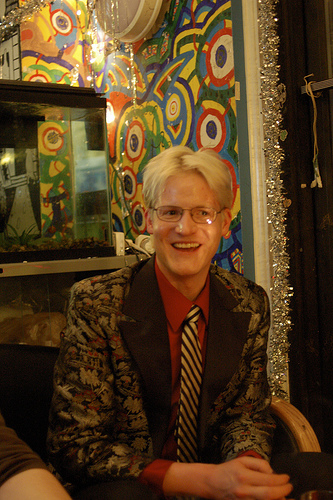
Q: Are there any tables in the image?
A: Yes, there is a table.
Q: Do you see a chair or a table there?
A: Yes, there is a table.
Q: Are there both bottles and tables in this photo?
A: No, there is a table but no bottles.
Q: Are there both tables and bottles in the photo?
A: No, there is a table but no bottles.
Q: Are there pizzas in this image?
A: No, there are no pizzas.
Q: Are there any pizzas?
A: No, there are no pizzas.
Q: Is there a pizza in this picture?
A: No, there are no pizzas.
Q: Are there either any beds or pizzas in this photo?
A: No, there are no pizzas or beds.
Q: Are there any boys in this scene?
A: No, there are no boys.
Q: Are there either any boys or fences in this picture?
A: No, there are no boys or fences.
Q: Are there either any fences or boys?
A: No, there are no boys or fences.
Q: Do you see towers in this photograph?
A: No, there are no towers.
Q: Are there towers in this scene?
A: No, there are no towers.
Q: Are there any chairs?
A: Yes, there is a chair.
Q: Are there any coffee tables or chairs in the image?
A: Yes, there is a chair.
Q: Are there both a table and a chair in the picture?
A: Yes, there are both a chair and a table.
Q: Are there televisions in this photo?
A: No, there are no televisions.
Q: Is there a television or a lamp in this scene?
A: No, there are no televisions or lamps.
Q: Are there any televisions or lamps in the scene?
A: No, there are no televisions or lamps.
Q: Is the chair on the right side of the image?
A: Yes, the chair is on the right of the image.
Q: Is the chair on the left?
A: No, the chair is on the right of the image.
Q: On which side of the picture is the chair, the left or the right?
A: The chair is on the right of the image.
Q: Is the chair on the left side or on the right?
A: The chair is on the right of the image.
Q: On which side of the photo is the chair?
A: The chair is on the right of the image.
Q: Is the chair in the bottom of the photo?
A: Yes, the chair is in the bottom of the image.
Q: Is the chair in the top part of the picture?
A: No, the chair is in the bottom of the image.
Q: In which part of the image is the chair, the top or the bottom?
A: The chair is in the bottom of the image.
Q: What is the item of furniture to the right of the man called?
A: The piece of furniture is a chair.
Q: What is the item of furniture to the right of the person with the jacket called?
A: The piece of furniture is a chair.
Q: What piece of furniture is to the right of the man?
A: The piece of furniture is a chair.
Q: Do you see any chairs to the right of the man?
A: Yes, there is a chair to the right of the man.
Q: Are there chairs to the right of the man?
A: Yes, there is a chair to the right of the man.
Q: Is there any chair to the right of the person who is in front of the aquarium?
A: Yes, there is a chair to the right of the man.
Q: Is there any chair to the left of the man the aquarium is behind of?
A: No, the chair is to the right of the man.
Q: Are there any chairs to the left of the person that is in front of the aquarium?
A: No, the chair is to the right of the man.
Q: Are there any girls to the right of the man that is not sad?
A: No, there is a chair to the right of the man.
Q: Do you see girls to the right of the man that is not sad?
A: No, there is a chair to the right of the man.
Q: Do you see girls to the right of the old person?
A: No, there is a chair to the right of the man.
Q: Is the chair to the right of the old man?
A: Yes, the chair is to the right of the man.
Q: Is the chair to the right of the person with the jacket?
A: Yes, the chair is to the right of the man.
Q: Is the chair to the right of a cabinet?
A: No, the chair is to the right of the man.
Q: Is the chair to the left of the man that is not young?
A: No, the chair is to the right of the man.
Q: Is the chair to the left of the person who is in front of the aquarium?
A: No, the chair is to the right of the man.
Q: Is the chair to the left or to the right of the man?
A: The chair is to the right of the man.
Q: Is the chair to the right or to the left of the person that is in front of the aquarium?
A: The chair is to the right of the man.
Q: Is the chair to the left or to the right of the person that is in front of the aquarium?
A: The chair is to the right of the man.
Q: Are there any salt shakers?
A: No, there are no salt shakers.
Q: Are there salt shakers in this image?
A: No, there are no salt shakers.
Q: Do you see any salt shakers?
A: No, there are no salt shakers.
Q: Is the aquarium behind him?
A: Yes, the aquarium is behind a man.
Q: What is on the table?
A: The aquarium is on the table.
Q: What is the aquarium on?
A: The aquarium is on the table.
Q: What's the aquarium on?
A: The aquarium is on the table.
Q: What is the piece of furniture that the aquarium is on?
A: The piece of furniture is a table.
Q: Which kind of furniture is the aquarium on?
A: The aquarium is on the table.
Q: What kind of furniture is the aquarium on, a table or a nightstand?
A: The aquarium is on a table.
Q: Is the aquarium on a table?
A: Yes, the aquarium is on a table.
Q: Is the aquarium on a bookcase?
A: No, the aquarium is on a table.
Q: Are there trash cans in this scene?
A: No, there are no trash cans.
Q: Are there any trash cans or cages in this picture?
A: No, there are no trash cans or cages.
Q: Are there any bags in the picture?
A: No, there are no bags.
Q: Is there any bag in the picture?
A: No, there are no bags.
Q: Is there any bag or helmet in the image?
A: No, there are no bags or helmets.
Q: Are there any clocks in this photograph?
A: Yes, there is a clock.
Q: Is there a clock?
A: Yes, there is a clock.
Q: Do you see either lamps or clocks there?
A: Yes, there is a clock.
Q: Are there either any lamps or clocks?
A: Yes, there is a clock.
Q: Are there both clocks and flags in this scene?
A: No, there is a clock but no flags.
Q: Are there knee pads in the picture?
A: No, there are no knee pads.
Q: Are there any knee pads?
A: No, there are no knee pads.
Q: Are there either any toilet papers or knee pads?
A: No, there are no knee pads or toilet papers.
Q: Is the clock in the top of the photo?
A: Yes, the clock is in the top of the image.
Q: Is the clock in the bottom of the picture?
A: No, the clock is in the top of the image.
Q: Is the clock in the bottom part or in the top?
A: The clock is in the top of the image.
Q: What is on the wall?
A: The clock is on the wall.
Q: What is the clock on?
A: The clock is on the wall.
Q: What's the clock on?
A: The clock is on the wall.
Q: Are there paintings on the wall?
A: No, there is a clock on the wall.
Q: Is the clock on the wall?
A: Yes, the clock is on the wall.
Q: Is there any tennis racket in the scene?
A: No, there are no rackets.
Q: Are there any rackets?
A: No, there are no rackets.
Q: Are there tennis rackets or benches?
A: No, there are no tennis rackets or benches.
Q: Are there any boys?
A: No, there are no boys.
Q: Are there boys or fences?
A: No, there are no boys or fences.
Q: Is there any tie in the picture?
A: Yes, there is a tie.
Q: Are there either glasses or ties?
A: Yes, there is a tie.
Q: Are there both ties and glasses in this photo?
A: Yes, there are both a tie and glasses.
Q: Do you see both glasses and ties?
A: Yes, there are both a tie and glasses.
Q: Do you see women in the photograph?
A: No, there are no women.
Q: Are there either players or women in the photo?
A: No, there are no women or players.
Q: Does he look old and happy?
A: Yes, the man is old and happy.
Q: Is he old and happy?
A: Yes, the man is old and happy.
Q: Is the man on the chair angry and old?
A: No, the man is old but happy.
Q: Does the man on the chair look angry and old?
A: No, the man is old but happy.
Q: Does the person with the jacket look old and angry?
A: No, the man is old but happy.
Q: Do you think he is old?
A: Yes, the man is old.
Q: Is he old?
A: Yes, the man is old.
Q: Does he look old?
A: Yes, the man is old.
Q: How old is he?
A: The man is old.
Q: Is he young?
A: No, the man is old.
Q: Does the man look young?
A: No, the man is old.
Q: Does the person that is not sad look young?
A: No, the man is old.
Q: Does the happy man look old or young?
A: The man is old.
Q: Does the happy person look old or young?
A: The man is old.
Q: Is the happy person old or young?
A: The man is old.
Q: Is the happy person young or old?
A: The man is old.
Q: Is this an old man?
A: Yes, this is an old man.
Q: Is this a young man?
A: No, this is an old man.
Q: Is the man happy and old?
A: Yes, the man is happy and old.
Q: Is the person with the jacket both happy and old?
A: Yes, the man is happy and old.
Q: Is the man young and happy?
A: No, the man is happy but old.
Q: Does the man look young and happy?
A: No, the man is happy but old.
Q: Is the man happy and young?
A: No, the man is happy but old.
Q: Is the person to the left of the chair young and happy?
A: No, the man is happy but old.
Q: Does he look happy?
A: Yes, the man is happy.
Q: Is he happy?
A: Yes, the man is happy.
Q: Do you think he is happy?
A: Yes, the man is happy.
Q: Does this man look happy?
A: Yes, the man is happy.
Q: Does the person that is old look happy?
A: Yes, the man is happy.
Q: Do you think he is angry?
A: No, the man is happy.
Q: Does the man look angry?
A: No, the man is happy.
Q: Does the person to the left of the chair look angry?
A: No, the man is happy.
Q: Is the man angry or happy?
A: The man is happy.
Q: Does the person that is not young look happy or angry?
A: The man is happy.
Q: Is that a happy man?
A: Yes, that is a happy man.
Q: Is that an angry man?
A: No, that is a happy man.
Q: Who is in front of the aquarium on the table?
A: The man is in front of the aquarium.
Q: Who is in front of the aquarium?
A: The man is in front of the aquarium.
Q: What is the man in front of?
A: The man is in front of the aquarium.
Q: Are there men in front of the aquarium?
A: Yes, there is a man in front of the aquarium.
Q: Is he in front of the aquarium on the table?
A: Yes, the man is in front of the aquarium.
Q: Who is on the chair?
A: The man is on the chair.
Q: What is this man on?
A: The man is on the chair.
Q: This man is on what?
A: The man is on the chair.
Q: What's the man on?
A: The man is on the chair.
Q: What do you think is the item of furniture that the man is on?
A: The piece of furniture is a chair.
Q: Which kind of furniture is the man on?
A: The man is on the chair.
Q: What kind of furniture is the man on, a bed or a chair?
A: The man is on a chair.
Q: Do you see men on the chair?
A: Yes, there is a man on the chair.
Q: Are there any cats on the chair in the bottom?
A: No, there is a man on the chair.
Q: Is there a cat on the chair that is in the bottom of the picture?
A: No, there is a man on the chair.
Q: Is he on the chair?
A: Yes, the man is on the chair.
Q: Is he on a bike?
A: No, the man is on the chair.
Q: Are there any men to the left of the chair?
A: Yes, there is a man to the left of the chair.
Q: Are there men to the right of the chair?
A: No, the man is to the left of the chair.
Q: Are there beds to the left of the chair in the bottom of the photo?
A: No, there is a man to the left of the chair.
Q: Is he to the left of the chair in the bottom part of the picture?
A: Yes, the man is to the left of the chair.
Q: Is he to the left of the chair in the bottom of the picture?
A: Yes, the man is to the left of the chair.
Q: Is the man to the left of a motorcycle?
A: No, the man is to the left of the chair.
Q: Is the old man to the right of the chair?
A: No, the man is to the left of the chair.